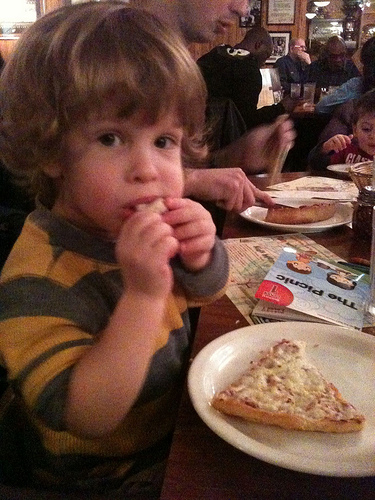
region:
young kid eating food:
[13, 14, 213, 414]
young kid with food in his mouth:
[25, 15, 215, 431]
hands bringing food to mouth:
[117, 189, 203, 277]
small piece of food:
[131, 189, 170, 220]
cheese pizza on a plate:
[207, 312, 372, 482]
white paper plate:
[196, 338, 373, 482]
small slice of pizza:
[219, 336, 347, 438]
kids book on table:
[248, 253, 361, 317]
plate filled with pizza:
[253, 188, 343, 225]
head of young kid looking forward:
[4, 14, 203, 232]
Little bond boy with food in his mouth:
[0, 0, 231, 497]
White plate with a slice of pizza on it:
[187, 317, 373, 475]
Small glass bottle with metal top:
[347, 183, 374, 264]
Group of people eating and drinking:
[193, 23, 374, 114]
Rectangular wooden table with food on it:
[156, 169, 374, 497]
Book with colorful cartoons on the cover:
[250, 244, 373, 332]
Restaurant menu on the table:
[208, 230, 358, 329]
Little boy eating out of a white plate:
[308, 87, 374, 178]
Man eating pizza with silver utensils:
[125, 0, 354, 234]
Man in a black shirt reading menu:
[194, 22, 298, 130]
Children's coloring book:
[253, 239, 373, 332]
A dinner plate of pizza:
[213, 323, 363, 436]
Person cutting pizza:
[205, 160, 350, 231]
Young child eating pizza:
[5, 3, 239, 446]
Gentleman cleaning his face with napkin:
[280, 28, 315, 92]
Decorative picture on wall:
[264, 0, 300, 25]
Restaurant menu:
[221, 226, 349, 284]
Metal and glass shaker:
[349, 170, 372, 277]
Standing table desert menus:
[283, 76, 324, 105]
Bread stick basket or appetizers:
[344, 158, 372, 187]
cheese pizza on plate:
[216, 338, 359, 435]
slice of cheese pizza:
[225, 341, 357, 439]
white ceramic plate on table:
[196, 319, 373, 474]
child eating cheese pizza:
[3, 101, 217, 499]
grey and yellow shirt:
[3, 199, 227, 450]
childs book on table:
[261, 243, 367, 328]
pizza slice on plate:
[266, 197, 329, 222]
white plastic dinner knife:
[270, 194, 333, 207]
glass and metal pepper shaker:
[354, 184, 373, 230]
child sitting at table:
[320, 96, 374, 164]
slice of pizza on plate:
[209, 336, 366, 432]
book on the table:
[249, 242, 373, 332]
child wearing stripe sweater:
[0, 0, 234, 498]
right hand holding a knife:
[181, 165, 354, 233]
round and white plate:
[187, 320, 373, 480]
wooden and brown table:
[159, 172, 373, 499]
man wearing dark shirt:
[196, 23, 299, 125]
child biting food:
[0, 2, 233, 499]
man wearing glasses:
[273, 37, 315, 83]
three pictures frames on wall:
[237, 0, 299, 65]